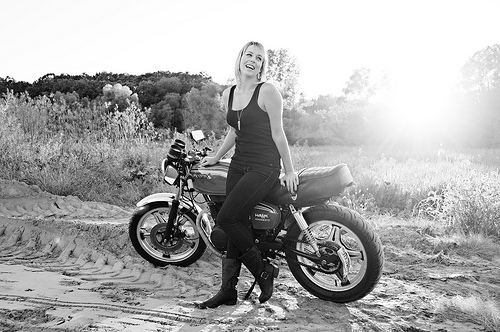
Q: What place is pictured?
A: It is a field.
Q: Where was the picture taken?
A: It was taken at the field.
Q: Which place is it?
A: It is a field.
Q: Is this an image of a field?
A: Yes, it is showing a field.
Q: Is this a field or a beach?
A: It is a field.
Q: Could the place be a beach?
A: No, it is a field.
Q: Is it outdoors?
A: Yes, it is outdoors.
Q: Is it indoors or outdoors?
A: It is outdoors.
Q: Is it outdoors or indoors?
A: It is outdoors.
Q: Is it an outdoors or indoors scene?
A: It is outdoors.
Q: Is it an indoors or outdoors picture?
A: It is outdoors.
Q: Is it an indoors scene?
A: No, it is outdoors.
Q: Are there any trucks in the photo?
A: No, there are no trucks.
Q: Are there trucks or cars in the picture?
A: No, there are no trucks or cars.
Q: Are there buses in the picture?
A: No, there are no buses.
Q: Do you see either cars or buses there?
A: No, there are no buses or cars.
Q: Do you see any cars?
A: No, there are no cars.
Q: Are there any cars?
A: No, there are no cars.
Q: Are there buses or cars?
A: No, there are no cars or buses.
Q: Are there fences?
A: No, there are no fences.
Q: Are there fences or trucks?
A: No, there are no fences or trucks.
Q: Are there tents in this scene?
A: No, there are no tents.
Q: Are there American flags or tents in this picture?
A: No, there are no tents or American flags.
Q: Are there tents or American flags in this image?
A: No, there are no tents or American flags.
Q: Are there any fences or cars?
A: No, there are no cars or fences.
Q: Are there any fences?
A: No, there are no fences.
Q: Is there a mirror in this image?
A: Yes, there is a mirror.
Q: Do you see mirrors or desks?
A: Yes, there is a mirror.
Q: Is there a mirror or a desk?
A: Yes, there is a mirror.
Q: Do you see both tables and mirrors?
A: No, there is a mirror but no tables.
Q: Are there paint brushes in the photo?
A: No, there are no paint brushes.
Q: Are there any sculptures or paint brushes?
A: No, there are no paint brushes or sculptures.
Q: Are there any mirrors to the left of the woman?
A: Yes, there is a mirror to the left of the woman.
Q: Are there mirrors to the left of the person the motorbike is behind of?
A: Yes, there is a mirror to the left of the woman.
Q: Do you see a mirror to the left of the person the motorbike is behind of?
A: Yes, there is a mirror to the left of the woman.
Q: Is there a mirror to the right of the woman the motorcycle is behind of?
A: No, the mirror is to the left of the woman.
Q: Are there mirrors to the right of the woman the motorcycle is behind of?
A: No, the mirror is to the left of the woman.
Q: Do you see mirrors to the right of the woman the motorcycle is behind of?
A: No, the mirror is to the left of the woman.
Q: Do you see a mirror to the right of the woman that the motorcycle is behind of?
A: No, the mirror is to the left of the woman.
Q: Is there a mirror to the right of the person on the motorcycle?
A: No, the mirror is to the left of the woman.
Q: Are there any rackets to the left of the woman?
A: No, there is a mirror to the left of the woman.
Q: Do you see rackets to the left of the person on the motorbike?
A: No, there is a mirror to the left of the woman.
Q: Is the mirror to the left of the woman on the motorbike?
A: Yes, the mirror is to the left of the woman.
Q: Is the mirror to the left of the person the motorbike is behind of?
A: Yes, the mirror is to the left of the woman.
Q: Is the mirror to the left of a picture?
A: No, the mirror is to the left of the woman.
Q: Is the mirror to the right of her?
A: No, the mirror is to the left of the woman.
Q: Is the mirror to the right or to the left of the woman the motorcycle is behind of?
A: The mirror is to the left of the woman.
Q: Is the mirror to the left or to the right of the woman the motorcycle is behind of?
A: The mirror is to the left of the woman.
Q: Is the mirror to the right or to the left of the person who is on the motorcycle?
A: The mirror is to the left of the woman.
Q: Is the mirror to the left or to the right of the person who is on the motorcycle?
A: The mirror is to the left of the woman.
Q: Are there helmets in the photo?
A: No, there are no helmets.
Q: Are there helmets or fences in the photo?
A: No, there are no helmets or fences.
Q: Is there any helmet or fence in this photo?
A: No, there are no helmets or fences.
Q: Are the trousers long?
A: Yes, the trousers are long.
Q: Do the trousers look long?
A: Yes, the trousers are long.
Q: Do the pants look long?
A: Yes, the pants are long.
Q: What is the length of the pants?
A: The pants are long.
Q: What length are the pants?
A: The pants are long.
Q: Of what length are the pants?
A: The pants are long.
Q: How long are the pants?
A: The pants are long.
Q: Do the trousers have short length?
A: No, the trousers are long.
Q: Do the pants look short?
A: No, the pants are long.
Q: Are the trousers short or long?
A: The trousers are long.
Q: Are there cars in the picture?
A: No, there are no cars.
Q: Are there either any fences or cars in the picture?
A: No, there are no cars or fences.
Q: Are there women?
A: Yes, there is a woman.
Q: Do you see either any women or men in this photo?
A: Yes, there is a woman.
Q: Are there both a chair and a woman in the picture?
A: No, there is a woman but no chairs.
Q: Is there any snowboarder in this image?
A: No, there are no snowboarders.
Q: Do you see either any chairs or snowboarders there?
A: No, there are no snowboarders or chairs.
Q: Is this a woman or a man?
A: This is a woman.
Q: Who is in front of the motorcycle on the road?
A: The woman is in front of the motorbike.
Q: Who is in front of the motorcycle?
A: The woman is in front of the motorbike.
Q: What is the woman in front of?
A: The woman is in front of the motorbike.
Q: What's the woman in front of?
A: The woman is in front of the motorbike.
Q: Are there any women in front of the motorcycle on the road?
A: Yes, there is a woman in front of the motorbike.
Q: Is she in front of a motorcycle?
A: Yes, the woman is in front of a motorcycle.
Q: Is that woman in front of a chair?
A: No, the woman is in front of a motorcycle.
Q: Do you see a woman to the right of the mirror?
A: Yes, there is a woman to the right of the mirror.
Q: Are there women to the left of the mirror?
A: No, the woman is to the right of the mirror.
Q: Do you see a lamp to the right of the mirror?
A: No, there is a woman to the right of the mirror.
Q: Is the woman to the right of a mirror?
A: Yes, the woman is to the right of a mirror.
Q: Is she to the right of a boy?
A: No, the woman is to the right of a mirror.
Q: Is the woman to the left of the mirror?
A: No, the woman is to the right of the mirror.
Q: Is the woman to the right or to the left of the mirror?
A: The woman is to the right of the mirror.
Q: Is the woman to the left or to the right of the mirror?
A: The woman is to the right of the mirror.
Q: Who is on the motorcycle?
A: The woman is on the motorcycle.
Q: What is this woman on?
A: The woman is on the motorbike.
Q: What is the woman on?
A: The woman is on the motorbike.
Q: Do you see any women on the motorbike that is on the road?
A: Yes, there is a woman on the motorbike.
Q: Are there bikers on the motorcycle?
A: No, there is a woman on the motorcycle.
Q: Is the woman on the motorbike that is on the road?
A: Yes, the woman is on the motorbike.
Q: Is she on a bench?
A: No, the woman is on the motorbike.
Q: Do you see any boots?
A: Yes, there are boots.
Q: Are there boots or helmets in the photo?
A: Yes, there are boots.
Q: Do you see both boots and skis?
A: No, there are boots but no skis.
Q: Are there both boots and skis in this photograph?
A: No, there are boots but no skis.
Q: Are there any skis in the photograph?
A: No, there are no skis.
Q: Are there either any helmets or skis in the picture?
A: No, there are no skis or helmets.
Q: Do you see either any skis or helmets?
A: No, there are no skis or helmets.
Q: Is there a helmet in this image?
A: No, there are no helmets.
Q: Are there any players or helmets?
A: No, there are no helmets or players.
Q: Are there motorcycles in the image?
A: Yes, there is a motorcycle.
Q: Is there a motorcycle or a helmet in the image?
A: Yes, there is a motorcycle.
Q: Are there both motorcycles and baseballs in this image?
A: No, there is a motorcycle but no baseballs.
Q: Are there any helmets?
A: No, there are no helmets.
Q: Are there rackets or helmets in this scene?
A: No, there are no helmets or rackets.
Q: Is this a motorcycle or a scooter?
A: This is a motorcycle.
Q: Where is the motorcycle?
A: The motorcycle is on the road.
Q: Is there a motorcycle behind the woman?
A: Yes, there is a motorcycle behind the woman.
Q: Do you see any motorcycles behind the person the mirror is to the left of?
A: Yes, there is a motorcycle behind the woman.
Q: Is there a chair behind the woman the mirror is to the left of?
A: No, there is a motorcycle behind the woman.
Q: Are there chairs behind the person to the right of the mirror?
A: No, there is a motorcycle behind the woman.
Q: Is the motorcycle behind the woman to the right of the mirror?
A: Yes, the motorcycle is behind the woman.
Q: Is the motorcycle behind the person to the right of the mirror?
A: Yes, the motorcycle is behind the woman.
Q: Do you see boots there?
A: Yes, there are boots.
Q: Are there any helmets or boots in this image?
A: Yes, there are boots.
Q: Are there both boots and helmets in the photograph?
A: No, there are boots but no helmets.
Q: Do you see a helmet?
A: No, there are no helmets.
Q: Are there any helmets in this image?
A: No, there are no helmets.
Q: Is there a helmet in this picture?
A: No, there are no helmets.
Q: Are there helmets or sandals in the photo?
A: No, there are no helmets or sandals.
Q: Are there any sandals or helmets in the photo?
A: No, there are no helmets or sandals.